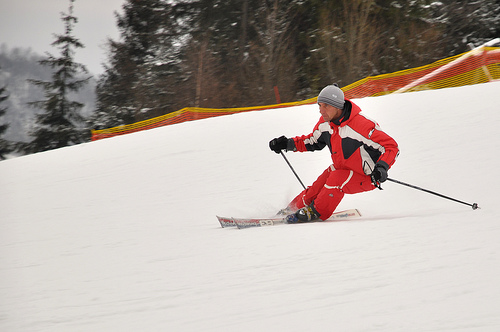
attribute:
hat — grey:
[321, 85, 355, 104]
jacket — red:
[318, 130, 390, 181]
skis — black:
[429, 172, 484, 217]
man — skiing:
[268, 92, 413, 224]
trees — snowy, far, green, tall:
[120, 29, 246, 92]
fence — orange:
[413, 63, 461, 84]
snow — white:
[93, 194, 186, 236]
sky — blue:
[31, 3, 66, 35]